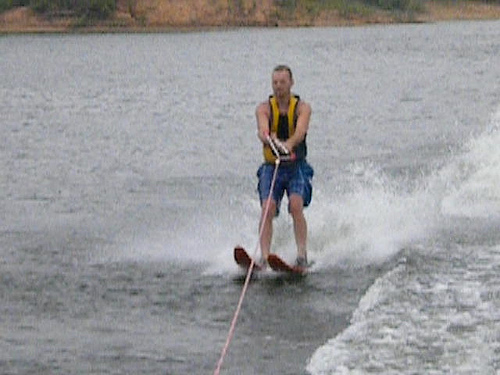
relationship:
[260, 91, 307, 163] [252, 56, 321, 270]
life vest on a man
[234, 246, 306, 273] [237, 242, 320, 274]
water skis on feet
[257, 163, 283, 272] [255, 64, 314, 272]
leg on a man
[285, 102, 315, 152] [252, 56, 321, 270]
arm on man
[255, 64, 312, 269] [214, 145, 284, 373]
man holding rope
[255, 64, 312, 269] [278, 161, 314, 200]
man wearing shorts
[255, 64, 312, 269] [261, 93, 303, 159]
man wearing vest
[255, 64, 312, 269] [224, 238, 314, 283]
man wearing skiis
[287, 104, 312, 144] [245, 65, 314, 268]
arm on man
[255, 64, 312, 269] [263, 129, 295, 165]
man holding on top object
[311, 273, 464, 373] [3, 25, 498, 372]
bubbles in water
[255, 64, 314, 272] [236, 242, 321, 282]
man wearing water skis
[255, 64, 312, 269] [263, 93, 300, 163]
man wearing life vest